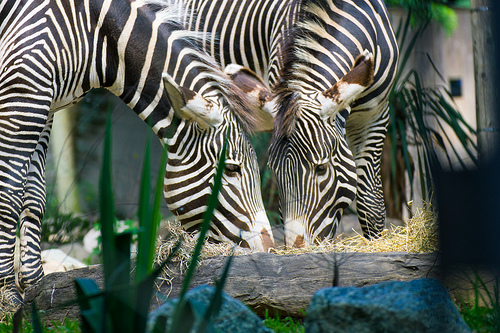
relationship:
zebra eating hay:
[0, 0, 278, 315] [147, 187, 439, 305]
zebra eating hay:
[157, 0, 400, 252] [147, 187, 439, 305]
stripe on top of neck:
[137, 26, 181, 125] [95, 0, 249, 147]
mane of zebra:
[268, 1, 330, 141] [157, 0, 400, 252]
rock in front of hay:
[24, 255, 499, 320] [147, 187, 439, 305]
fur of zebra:
[0, 1, 275, 312] [0, 0, 278, 315]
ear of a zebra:
[318, 48, 377, 118] [157, 0, 400, 252]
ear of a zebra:
[223, 62, 275, 116] [157, 0, 400, 252]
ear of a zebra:
[159, 70, 222, 130] [0, 0, 278, 315]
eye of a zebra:
[219, 158, 244, 179] [0, 0, 278, 315]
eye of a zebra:
[310, 158, 332, 178] [157, 0, 400, 252]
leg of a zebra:
[0, 106, 49, 317] [0, 0, 278, 315]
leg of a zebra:
[18, 112, 54, 300] [0, 0, 278, 315]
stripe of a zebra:
[86, 0, 112, 89] [0, 0, 278, 315]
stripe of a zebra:
[137, 26, 181, 125] [0, 0, 278, 315]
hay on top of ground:
[147, 187, 439, 305] [0, 213, 498, 331]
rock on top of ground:
[297, 279, 470, 332] [0, 213, 498, 331]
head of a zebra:
[160, 98, 275, 252] [0, 0, 278, 315]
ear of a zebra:
[247, 100, 277, 133] [0, 0, 278, 315]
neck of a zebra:
[266, 1, 365, 131] [157, 0, 400, 252]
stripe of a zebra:
[290, 16, 356, 66] [157, 0, 400, 252]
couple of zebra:
[2, 1, 400, 313] [0, 0, 275, 317]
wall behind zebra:
[71, 0, 480, 220] [157, 0, 400, 252]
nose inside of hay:
[245, 209, 278, 253] [147, 187, 439, 305]